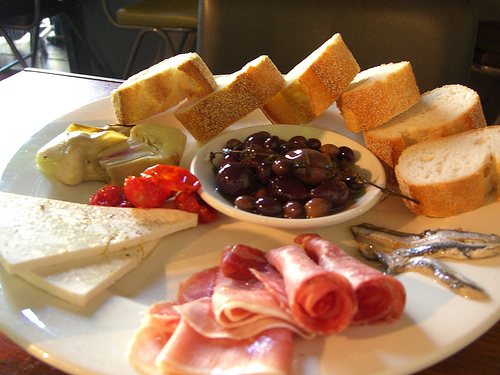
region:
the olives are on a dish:
[215, 134, 365, 215]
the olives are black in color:
[214, 128, 368, 217]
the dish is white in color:
[193, 130, 385, 226]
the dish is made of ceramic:
[189, 123, 385, 228]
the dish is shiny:
[189, 124, 388, 226]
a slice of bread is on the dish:
[403, 127, 499, 214]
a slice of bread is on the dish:
[367, 79, 484, 162]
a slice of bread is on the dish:
[341, 54, 421, 129]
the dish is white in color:
[3, 70, 493, 370]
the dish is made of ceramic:
[0, 89, 493, 373]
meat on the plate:
[251, 256, 362, 316]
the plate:
[353, 335, 395, 367]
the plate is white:
[76, 324, 126, 352]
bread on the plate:
[408, 145, 479, 202]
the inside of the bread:
[421, 151, 467, 172]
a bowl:
[346, 200, 361, 215]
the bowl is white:
[288, 216, 303, 228]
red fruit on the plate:
[128, 168, 193, 201]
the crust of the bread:
[208, 95, 243, 119]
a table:
[21, 75, 80, 111]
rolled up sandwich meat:
[147, 233, 387, 372]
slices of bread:
[176, 51, 430, 123]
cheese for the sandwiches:
[6, 176, 168, 313]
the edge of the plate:
[365, 322, 482, 367]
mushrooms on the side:
[39, 115, 189, 176]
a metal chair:
[93, 3, 177, 59]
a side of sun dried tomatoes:
[93, 175, 203, 217]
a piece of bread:
[411, 141, 498, 210]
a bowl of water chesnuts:
[207, 126, 374, 211]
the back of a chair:
[206, 5, 471, 91]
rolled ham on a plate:
[212, 235, 407, 336]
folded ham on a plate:
[136, 268, 291, 373]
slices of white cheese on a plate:
[1, 193, 197, 305]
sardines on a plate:
[351, 222, 498, 307]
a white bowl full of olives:
[191, 124, 383, 225]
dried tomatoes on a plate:
[90, 164, 217, 225]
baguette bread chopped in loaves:
[113, 32, 498, 214]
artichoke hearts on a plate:
[35, 116, 186, 183]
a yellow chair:
[101, 4, 197, 74]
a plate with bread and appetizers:
[3, 30, 497, 370]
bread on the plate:
[86, 40, 214, 116]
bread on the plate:
[182, 45, 284, 136]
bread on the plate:
[263, 25, 362, 117]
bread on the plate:
[340, 58, 417, 130]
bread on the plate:
[395, 120, 497, 227]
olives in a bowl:
[218, 131, 361, 218]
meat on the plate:
[126, 229, 397, 371]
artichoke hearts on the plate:
[34, 122, 184, 187]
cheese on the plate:
[3, 184, 210, 314]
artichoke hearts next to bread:
[36, 115, 190, 192]